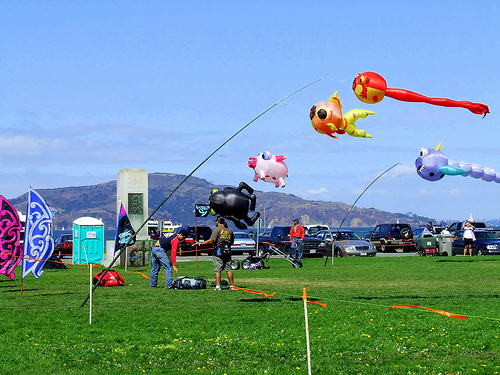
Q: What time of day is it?
A: Daytime.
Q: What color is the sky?
A: Blue.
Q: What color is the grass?
A: Green.